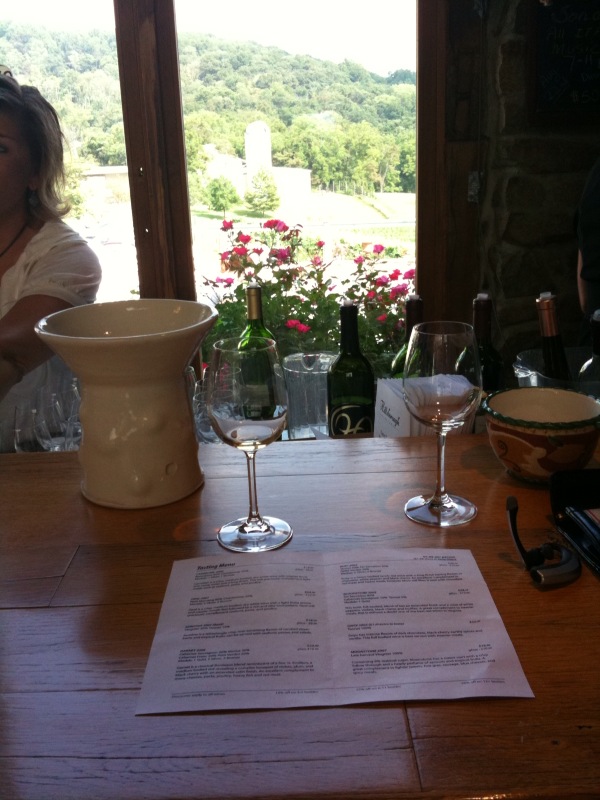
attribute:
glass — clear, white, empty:
[198, 317, 323, 533]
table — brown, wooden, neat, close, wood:
[11, 514, 165, 650]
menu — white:
[158, 554, 534, 716]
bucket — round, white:
[34, 280, 228, 490]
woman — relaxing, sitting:
[0, 88, 102, 319]